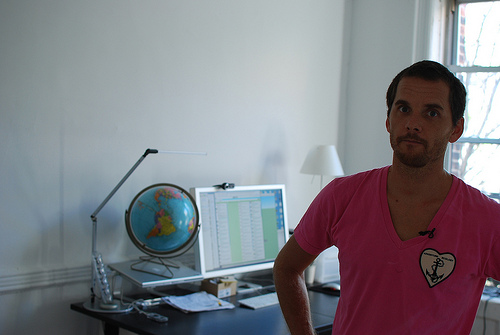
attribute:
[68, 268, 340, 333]
table — black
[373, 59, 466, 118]
hair — short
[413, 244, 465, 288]
logo — black, white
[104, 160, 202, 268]
globe — small , blue  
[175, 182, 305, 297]
screen — large 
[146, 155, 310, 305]
computer — silver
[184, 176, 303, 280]
frame — grey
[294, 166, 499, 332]
shirt — pink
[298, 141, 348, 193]
lamp — white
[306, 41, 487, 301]
man — unshaven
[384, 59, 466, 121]
hair — dark